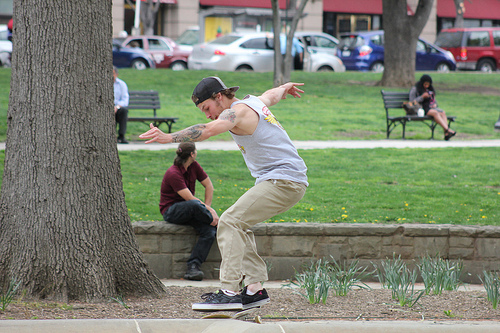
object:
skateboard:
[199, 306, 265, 323]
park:
[0, 65, 499, 331]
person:
[158, 134, 220, 280]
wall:
[133, 224, 497, 285]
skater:
[137, 74, 309, 312]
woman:
[407, 75, 456, 142]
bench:
[379, 90, 458, 139]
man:
[112, 65, 130, 145]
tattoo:
[166, 122, 205, 145]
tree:
[0, 1, 166, 296]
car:
[335, 29, 458, 74]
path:
[117, 139, 499, 151]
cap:
[190, 75, 239, 107]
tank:
[226, 93, 311, 187]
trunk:
[0, 10, 168, 304]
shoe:
[190, 289, 245, 311]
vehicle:
[189, 30, 347, 75]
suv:
[432, 26, 499, 71]